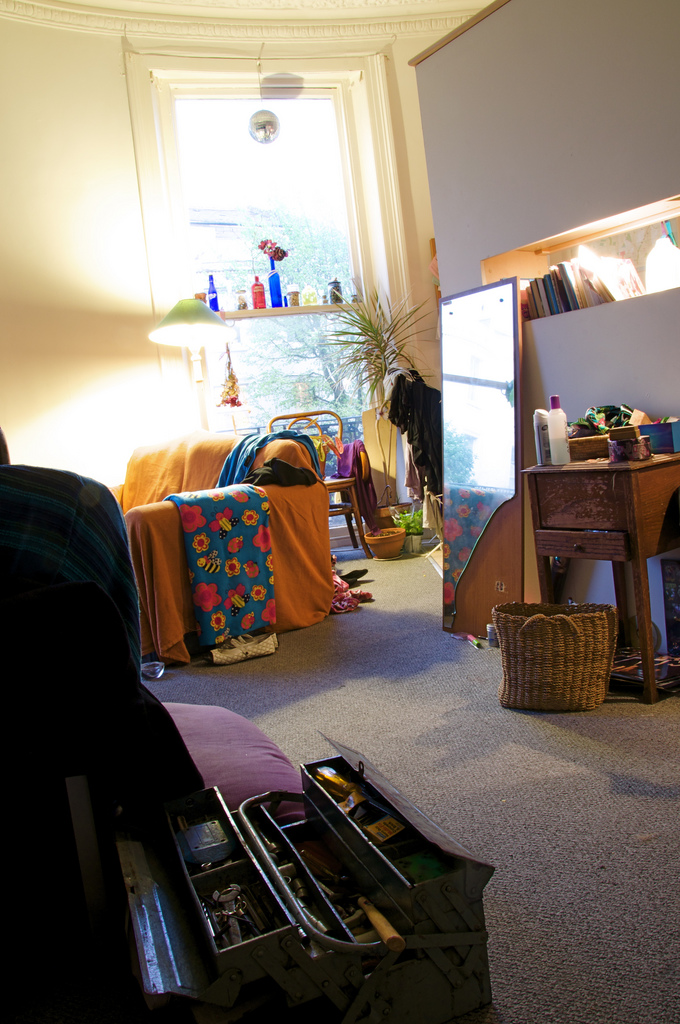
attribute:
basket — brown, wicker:
[473, 590, 622, 711]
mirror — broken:
[428, 272, 544, 650]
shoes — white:
[199, 623, 286, 668]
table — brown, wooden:
[518, 441, 656, 714]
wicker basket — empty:
[487, 584, 618, 717]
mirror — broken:
[418, 259, 547, 647]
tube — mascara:
[457, 621, 497, 651]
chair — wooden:
[279, 387, 374, 571]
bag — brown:
[453, 558, 627, 703]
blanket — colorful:
[158, 464, 336, 672]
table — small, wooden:
[479, 385, 659, 760]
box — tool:
[121, 749, 520, 1019]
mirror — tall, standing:
[409, 257, 596, 761]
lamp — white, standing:
[127, 277, 275, 504]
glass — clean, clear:
[218, 307, 361, 433]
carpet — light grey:
[325, 677, 676, 958]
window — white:
[167, 73, 377, 441]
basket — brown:
[484, 582, 654, 732]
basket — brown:
[491, 577, 639, 713]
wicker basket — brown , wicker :
[481, 584, 630, 728]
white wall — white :
[411, 7, 678, 245]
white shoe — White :
[199, 618, 291, 667]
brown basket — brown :
[474, 581, 631, 719]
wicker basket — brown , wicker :
[479, 577, 629, 734]